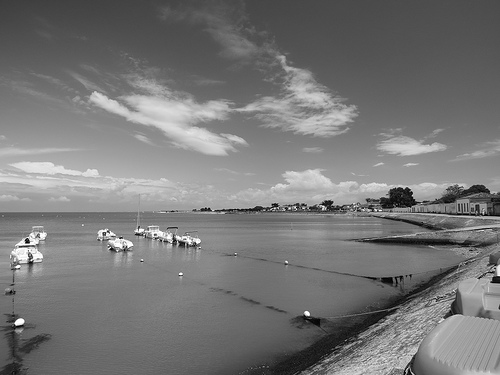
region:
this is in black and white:
[13, 10, 430, 339]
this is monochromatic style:
[18, 42, 458, 368]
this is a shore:
[95, 255, 340, 346]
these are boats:
[40, 200, 225, 273]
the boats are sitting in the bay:
[25, 213, 195, 290]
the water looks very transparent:
[85, 270, 350, 372]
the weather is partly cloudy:
[61, 40, 387, 180]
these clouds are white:
[43, 40, 391, 198]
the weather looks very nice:
[61, 16, 496, 199]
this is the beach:
[393, 272, 488, 368]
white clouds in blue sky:
[38, 21, 112, 53]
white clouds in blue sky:
[21, 38, 105, 102]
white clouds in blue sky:
[32, 93, 99, 153]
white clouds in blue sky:
[131, 56, 232, 116]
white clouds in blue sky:
[124, 123, 185, 163]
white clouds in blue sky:
[205, 26, 256, 74]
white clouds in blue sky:
[215, 136, 286, 211]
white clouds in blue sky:
[305, 38, 396, 143]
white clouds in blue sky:
[378, 21, 452, 98]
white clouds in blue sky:
[245, 73, 322, 160]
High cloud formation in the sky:
[42, 6, 364, 163]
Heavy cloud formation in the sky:
[0, 158, 499, 210]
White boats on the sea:
[6, 217, 204, 264]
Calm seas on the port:
[1, 211, 467, 374]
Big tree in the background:
[380, 185, 417, 209]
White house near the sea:
[453, 188, 498, 218]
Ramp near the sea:
[353, 219, 498, 244]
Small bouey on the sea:
[176, 270, 188, 278]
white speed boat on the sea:
[10, 243, 45, 265]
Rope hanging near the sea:
[313, 286, 458, 323]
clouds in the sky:
[241, 59, 364, 141]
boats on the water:
[92, 225, 139, 260]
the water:
[85, 294, 208, 368]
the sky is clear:
[348, 29, 455, 103]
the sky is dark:
[355, 28, 442, 106]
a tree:
[388, 181, 415, 205]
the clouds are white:
[277, 173, 333, 195]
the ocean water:
[65, 290, 200, 348]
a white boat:
[5, 245, 43, 261]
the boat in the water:
[105, 233, 140, 256]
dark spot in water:
[213, 283, 240, 312]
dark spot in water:
[165, 301, 218, 358]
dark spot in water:
[128, 298, 160, 320]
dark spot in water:
[310, 244, 332, 268]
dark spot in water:
[330, 261, 353, 273]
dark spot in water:
[353, 274, 390, 288]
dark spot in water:
[59, 246, 90, 276]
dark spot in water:
[33, 340, 63, 355]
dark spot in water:
[53, 257, 89, 299]